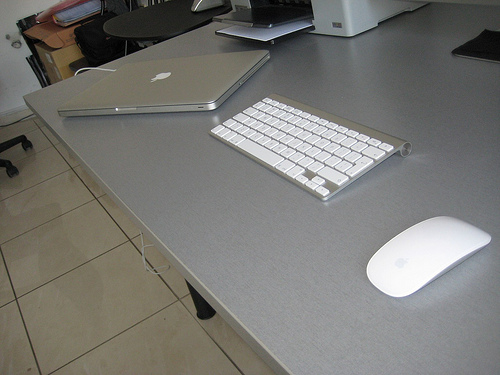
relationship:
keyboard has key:
[257, 132, 270, 146] [205, 93, 413, 200]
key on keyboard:
[205, 93, 413, 200] [257, 132, 270, 146]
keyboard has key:
[257, 132, 270, 146] [276, 160, 296, 174]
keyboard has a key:
[257, 132, 270, 146] [276, 160, 296, 174]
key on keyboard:
[276, 160, 296, 174] [257, 132, 270, 146]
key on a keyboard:
[205, 93, 413, 200] [257, 132, 270, 146]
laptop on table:
[53, 47, 272, 111] [28, 14, 496, 374]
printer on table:
[193, 2, 453, 51] [28, 14, 496, 374]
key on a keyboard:
[317, 168, 350, 185] [257, 132, 270, 146]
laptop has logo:
[53, 47, 272, 111] [146, 66, 173, 87]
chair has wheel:
[3, 125, 38, 187] [18, 138, 38, 160]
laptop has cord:
[53, 47, 272, 111] [74, 57, 119, 84]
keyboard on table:
[257, 132, 270, 146] [28, 14, 496, 374]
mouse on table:
[365, 207, 495, 308] [28, 14, 496, 374]